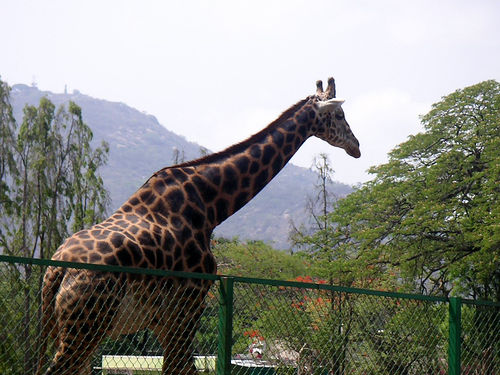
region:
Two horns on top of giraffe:
[313, 73, 337, 95]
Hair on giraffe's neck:
[129, 95, 316, 169]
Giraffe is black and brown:
[33, 75, 361, 371]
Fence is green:
[0, 251, 496, 371]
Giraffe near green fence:
[0, 72, 497, 372]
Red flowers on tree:
[291, 273, 330, 285]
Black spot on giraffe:
[163, 188, 185, 213]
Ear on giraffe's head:
[318, 96, 343, 113]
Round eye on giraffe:
[336, 111, 345, 121]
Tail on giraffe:
[34, 256, 59, 374]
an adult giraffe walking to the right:
[31, 56, 388, 363]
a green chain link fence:
[227, 277, 432, 369]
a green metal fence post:
[212, 276, 244, 373]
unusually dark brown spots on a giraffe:
[139, 212, 198, 254]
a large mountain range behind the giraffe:
[65, 114, 210, 181]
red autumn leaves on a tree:
[283, 263, 357, 315]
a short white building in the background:
[96, 346, 231, 372]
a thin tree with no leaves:
[307, 149, 352, 258]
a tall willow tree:
[8, 103, 105, 223]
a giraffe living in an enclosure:
[29, 39, 496, 371]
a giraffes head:
[297, 65, 378, 167]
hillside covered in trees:
[0, 60, 217, 226]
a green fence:
[226, 280, 472, 367]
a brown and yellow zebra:
[20, 46, 422, 366]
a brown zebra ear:
[315, 90, 350, 112]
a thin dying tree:
[277, 145, 374, 352]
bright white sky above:
[200, 22, 310, 83]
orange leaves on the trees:
[286, 257, 347, 339]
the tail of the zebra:
[31, 240, 71, 367]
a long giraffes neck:
[167, 92, 330, 222]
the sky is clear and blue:
[67, 29, 267, 156]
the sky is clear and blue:
[64, 22, 286, 267]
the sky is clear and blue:
[115, 54, 252, 232]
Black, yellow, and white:
[86, 75, 416, 273]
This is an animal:
[35, 70, 473, 331]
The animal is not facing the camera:
[25, 65, 412, 350]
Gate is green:
[19, 209, 454, 370]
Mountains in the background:
[11, 44, 479, 372]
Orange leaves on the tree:
[241, 236, 413, 347]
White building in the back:
[62, 304, 274, 371]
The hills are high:
[12, 25, 367, 262]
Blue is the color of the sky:
[47, 16, 417, 181]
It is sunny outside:
[82, 58, 446, 235]